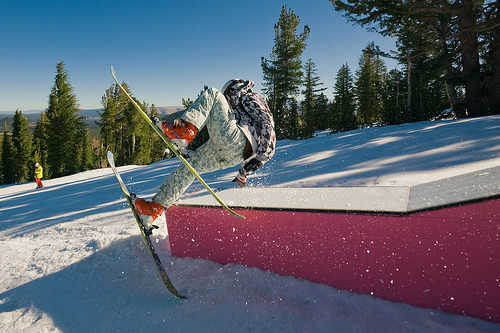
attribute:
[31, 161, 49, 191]
skier — dressed, losing, lonely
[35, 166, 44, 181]
jacket — yellow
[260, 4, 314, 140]
tree — tall, green, pine, giant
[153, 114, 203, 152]
ski boot — white, red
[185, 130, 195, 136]
accent — white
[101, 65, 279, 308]
skier — falling, trying, performing, wiping out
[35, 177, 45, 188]
pants — red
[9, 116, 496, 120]
horizon — framed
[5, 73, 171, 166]
trees — tall, pine, evergreen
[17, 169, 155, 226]
shadows — made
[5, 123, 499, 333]
snow — flying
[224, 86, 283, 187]
jacket — houndstooth, check, black, white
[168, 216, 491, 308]
base — red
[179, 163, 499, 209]
top — white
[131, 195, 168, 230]
snow boot — red, white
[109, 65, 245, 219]
ski — yellow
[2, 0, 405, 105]
sky — blue, bright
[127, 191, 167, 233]
ski boot — red